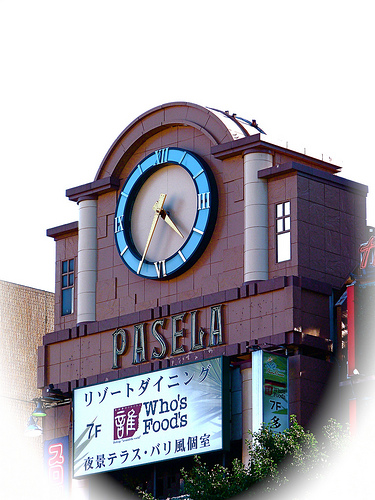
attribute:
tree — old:
[173, 407, 360, 495]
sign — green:
[249, 349, 290, 450]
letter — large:
[187, 307, 206, 353]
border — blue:
[112, 146, 219, 281]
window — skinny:
[261, 189, 311, 258]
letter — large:
[150, 319, 169, 362]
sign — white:
[196, 400, 216, 410]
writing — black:
[135, 389, 213, 436]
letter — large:
[108, 324, 131, 372]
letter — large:
[208, 307, 222, 345]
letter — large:
[168, 311, 189, 356]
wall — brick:
[54, 108, 298, 358]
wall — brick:
[2, 283, 52, 396]